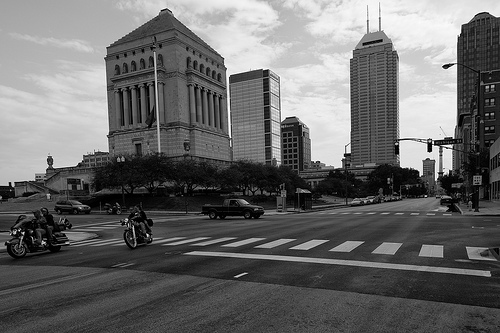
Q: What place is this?
A: It is a street.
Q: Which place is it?
A: It is a street.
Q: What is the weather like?
A: It is cloudy.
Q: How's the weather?
A: It is cloudy.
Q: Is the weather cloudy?
A: Yes, it is cloudy.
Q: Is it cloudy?
A: Yes, it is cloudy.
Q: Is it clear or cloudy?
A: It is cloudy.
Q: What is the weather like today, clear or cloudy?
A: It is cloudy.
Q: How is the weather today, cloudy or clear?
A: It is cloudy.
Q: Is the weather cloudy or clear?
A: It is cloudy.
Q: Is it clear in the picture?
A: No, it is cloudy.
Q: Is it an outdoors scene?
A: Yes, it is outdoors.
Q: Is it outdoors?
A: Yes, it is outdoors.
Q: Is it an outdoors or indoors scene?
A: It is outdoors.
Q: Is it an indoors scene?
A: No, it is outdoors.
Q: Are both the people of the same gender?
A: No, they are both male and female.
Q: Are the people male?
A: No, they are both male and female.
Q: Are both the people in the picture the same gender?
A: No, they are both male and female.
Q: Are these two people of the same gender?
A: No, they are both male and female.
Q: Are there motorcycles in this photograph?
A: Yes, there is a motorcycle.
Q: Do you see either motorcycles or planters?
A: Yes, there is a motorcycle.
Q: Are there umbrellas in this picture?
A: No, there are no umbrellas.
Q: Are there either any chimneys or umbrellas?
A: No, there are no umbrellas or chimneys.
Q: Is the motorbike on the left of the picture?
A: Yes, the motorbike is on the left of the image.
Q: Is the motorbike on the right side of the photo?
A: No, the motorbike is on the left of the image.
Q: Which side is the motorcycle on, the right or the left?
A: The motorcycle is on the left of the image.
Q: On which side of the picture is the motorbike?
A: The motorbike is on the left of the image.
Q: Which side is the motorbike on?
A: The motorbike is on the left of the image.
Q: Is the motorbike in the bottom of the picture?
A: Yes, the motorbike is in the bottom of the image.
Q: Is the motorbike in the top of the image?
A: No, the motorbike is in the bottom of the image.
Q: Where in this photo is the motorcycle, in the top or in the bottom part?
A: The motorcycle is in the bottom of the image.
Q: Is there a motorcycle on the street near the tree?
A: Yes, there is a motorcycle on the street.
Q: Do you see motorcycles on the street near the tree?
A: Yes, there is a motorcycle on the street.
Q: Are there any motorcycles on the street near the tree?
A: Yes, there is a motorcycle on the street.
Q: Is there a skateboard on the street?
A: No, there is a motorcycle on the street.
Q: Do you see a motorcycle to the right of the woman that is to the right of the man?
A: Yes, there is a motorcycle to the right of the woman.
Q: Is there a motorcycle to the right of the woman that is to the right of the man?
A: Yes, there is a motorcycle to the right of the woman.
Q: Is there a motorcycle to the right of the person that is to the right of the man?
A: Yes, there is a motorcycle to the right of the woman.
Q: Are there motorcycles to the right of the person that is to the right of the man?
A: Yes, there is a motorcycle to the right of the woman.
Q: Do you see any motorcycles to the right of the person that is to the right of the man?
A: Yes, there is a motorcycle to the right of the woman.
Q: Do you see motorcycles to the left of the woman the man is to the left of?
A: No, the motorcycle is to the right of the woman.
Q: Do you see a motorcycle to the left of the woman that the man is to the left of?
A: No, the motorcycle is to the right of the woman.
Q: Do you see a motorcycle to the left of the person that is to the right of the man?
A: No, the motorcycle is to the right of the woman.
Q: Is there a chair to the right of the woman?
A: No, there is a motorcycle to the right of the woman.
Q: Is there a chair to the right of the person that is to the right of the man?
A: No, there is a motorcycle to the right of the woman.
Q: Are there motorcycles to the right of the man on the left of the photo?
A: Yes, there is a motorcycle to the right of the man.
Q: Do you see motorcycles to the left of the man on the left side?
A: No, the motorcycle is to the right of the man.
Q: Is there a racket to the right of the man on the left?
A: No, there is a motorcycle to the right of the man.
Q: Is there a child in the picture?
A: No, there are no children.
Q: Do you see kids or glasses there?
A: No, there are no kids or glasses.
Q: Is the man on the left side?
A: Yes, the man is on the left of the image.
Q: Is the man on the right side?
A: No, the man is on the left of the image.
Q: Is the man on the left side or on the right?
A: The man is on the left of the image.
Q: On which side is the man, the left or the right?
A: The man is on the left of the image.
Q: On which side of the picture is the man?
A: The man is on the left of the image.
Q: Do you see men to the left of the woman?
A: Yes, there is a man to the left of the woman.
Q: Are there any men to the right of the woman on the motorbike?
A: No, the man is to the left of the woman.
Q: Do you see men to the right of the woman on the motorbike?
A: No, the man is to the left of the woman.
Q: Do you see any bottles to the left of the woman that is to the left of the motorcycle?
A: No, there is a man to the left of the woman.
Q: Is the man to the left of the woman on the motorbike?
A: Yes, the man is to the left of the woman.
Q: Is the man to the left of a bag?
A: No, the man is to the left of the woman.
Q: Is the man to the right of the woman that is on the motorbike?
A: No, the man is to the left of the woman.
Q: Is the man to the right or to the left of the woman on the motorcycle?
A: The man is to the left of the woman.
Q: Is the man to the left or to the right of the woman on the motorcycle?
A: The man is to the left of the woman.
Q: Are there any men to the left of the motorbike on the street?
A: Yes, there is a man to the left of the motorcycle.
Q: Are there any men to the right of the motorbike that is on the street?
A: No, the man is to the left of the motorcycle.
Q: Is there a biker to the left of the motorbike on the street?
A: No, there is a man to the left of the motorbike.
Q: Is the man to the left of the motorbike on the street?
A: Yes, the man is to the left of the motorcycle.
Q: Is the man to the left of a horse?
A: No, the man is to the left of the motorcycle.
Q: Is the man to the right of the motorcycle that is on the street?
A: No, the man is to the left of the motorcycle.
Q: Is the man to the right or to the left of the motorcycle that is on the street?
A: The man is to the left of the motorbike.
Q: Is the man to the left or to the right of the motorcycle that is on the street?
A: The man is to the left of the motorbike.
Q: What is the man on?
A: The man is on the motorbike.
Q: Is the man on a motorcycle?
A: Yes, the man is on a motorcycle.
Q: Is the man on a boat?
A: No, the man is on a motorcycle.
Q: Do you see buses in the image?
A: No, there are no buses.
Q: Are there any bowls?
A: No, there are no bowls.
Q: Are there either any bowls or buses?
A: No, there are no bowls or buses.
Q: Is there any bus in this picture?
A: No, there are no buses.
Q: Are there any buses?
A: No, there are no buses.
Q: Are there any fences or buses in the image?
A: No, there are no buses or fences.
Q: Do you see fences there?
A: No, there are no fences.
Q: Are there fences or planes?
A: No, there are no fences or planes.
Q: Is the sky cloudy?
A: Yes, the sky is cloudy.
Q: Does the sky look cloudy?
A: Yes, the sky is cloudy.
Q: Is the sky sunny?
A: No, the sky is cloudy.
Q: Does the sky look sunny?
A: No, the sky is cloudy.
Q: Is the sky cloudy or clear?
A: The sky is cloudy.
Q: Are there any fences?
A: No, there are no fences.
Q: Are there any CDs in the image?
A: No, there are no cds.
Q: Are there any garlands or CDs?
A: No, there are no CDs or garlands.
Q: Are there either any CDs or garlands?
A: No, there are no CDs or garlands.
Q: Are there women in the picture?
A: Yes, there is a woman.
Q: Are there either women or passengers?
A: Yes, there is a woman.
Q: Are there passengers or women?
A: Yes, there is a woman.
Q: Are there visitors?
A: No, there are no visitors.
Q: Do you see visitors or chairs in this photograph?
A: No, there are no visitors or chairs.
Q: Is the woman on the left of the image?
A: Yes, the woman is on the left of the image.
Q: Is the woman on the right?
A: No, the woman is on the left of the image.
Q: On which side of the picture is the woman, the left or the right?
A: The woman is on the left of the image.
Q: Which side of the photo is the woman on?
A: The woman is on the left of the image.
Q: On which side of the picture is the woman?
A: The woman is on the left of the image.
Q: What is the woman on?
A: The woman is on the motorbike.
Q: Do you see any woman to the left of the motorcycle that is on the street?
A: Yes, there is a woman to the left of the motorcycle.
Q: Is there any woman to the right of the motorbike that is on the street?
A: No, the woman is to the left of the motorbike.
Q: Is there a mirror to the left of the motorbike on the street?
A: No, there is a woman to the left of the motorcycle.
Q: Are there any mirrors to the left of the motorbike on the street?
A: No, there is a woman to the left of the motorcycle.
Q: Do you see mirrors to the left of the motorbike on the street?
A: No, there is a woman to the left of the motorcycle.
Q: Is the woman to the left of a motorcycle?
A: Yes, the woman is to the left of a motorcycle.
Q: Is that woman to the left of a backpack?
A: No, the woman is to the left of a motorcycle.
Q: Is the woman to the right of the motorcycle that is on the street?
A: No, the woman is to the left of the motorcycle.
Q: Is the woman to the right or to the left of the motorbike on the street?
A: The woman is to the left of the motorcycle.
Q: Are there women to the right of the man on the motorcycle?
A: Yes, there is a woman to the right of the man.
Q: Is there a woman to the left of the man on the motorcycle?
A: No, the woman is to the right of the man.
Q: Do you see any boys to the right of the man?
A: No, there is a woman to the right of the man.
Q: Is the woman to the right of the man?
A: Yes, the woman is to the right of the man.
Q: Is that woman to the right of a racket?
A: No, the woman is to the right of the man.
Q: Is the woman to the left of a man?
A: No, the woman is to the right of a man.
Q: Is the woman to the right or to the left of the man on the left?
A: The woman is to the right of the man.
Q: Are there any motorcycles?
A: Yes, there is a motorcycle.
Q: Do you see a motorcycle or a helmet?
A: Yes, there is a motorcycle.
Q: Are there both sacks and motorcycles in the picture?
A: No, there is a motorcycle but no sacks.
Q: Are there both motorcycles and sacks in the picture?
A: No, there is a motorcycle but no sacks.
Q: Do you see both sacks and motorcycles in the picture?
A: No, there is a motorcycle but no sacks.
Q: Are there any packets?
A: No, there are no packets.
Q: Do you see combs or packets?
A: No, there are no packets or combs.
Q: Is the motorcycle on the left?
A: Yes, the motorcycle is on the left of the image.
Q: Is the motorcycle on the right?
A: No, the motorcycle is on the left of the image.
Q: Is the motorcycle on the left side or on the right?
A: The motorcycle is on the left of the image.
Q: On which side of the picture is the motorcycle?
A: The motorcycle is on the left of the image.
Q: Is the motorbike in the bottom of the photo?
A: Yes, the motorbike is in the bottom of the image.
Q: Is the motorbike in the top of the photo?
A: No, the motorbike is in the bottom of the image.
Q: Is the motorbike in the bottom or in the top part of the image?
A: The motorbike is in the bottom of the image.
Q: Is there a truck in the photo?
A: Yes, there is a truck.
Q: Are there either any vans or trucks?
A: Yes, there is a truck.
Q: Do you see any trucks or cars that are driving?
A: Yes, the truck is driving.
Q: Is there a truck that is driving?
A: Yes, there is a truck that is driving.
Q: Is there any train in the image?
A: No, there are no trains.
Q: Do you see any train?
A: No, there are no trains.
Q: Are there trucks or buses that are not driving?
A: No, there is a truck but it is driving.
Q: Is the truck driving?
A: Yes, the truck is driving.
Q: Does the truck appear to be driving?
A: Yes, the truck is driving.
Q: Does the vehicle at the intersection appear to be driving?
A: Yes, the truck is driving.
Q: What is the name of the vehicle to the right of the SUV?
A: The vehicle is a truck.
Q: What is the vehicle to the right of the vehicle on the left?
A: The vehicle is a truck.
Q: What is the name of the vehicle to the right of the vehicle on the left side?
A: The vehicle is a truck.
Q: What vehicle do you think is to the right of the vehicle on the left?
A: The vehicle is a truck.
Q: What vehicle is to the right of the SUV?
A: The vehicle is a truck.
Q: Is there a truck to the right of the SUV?
A: Yes, there is a truck to the right of the SUV.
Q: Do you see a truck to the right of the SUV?
A: Yes, there is a truck to the right of the SUV.